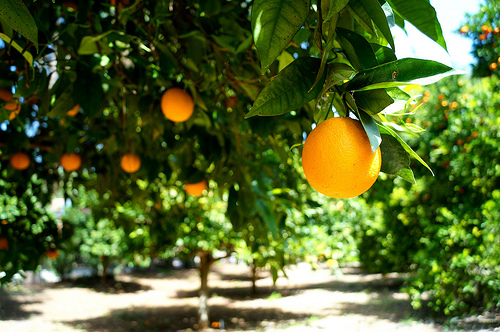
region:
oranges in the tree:
[5, 61, 368, 191]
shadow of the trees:
[103, 294, 278, 329]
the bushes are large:
[410, 138, 484, 307]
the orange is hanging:
[310, 123, 377, 194]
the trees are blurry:
[80, 210, 236, 290]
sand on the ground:
[303, 279, 368, 318]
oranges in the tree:
[0, 131, 186, 167]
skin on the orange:
[316, 145, 351, 197]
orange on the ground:
[209, 318, 229, 324]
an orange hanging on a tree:
[296, 109, 383, 202]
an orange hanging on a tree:
[159, 86, 198, 123]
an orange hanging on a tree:
[119, 150, 142, 175]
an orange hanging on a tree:
[179, 171, 209, 199]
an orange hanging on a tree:
[58, 147, 83, 173]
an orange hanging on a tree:
[10, 152, 27, 170]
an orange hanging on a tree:
[0, 88, 27, 122]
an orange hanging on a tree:
[43, 247, 60, 259]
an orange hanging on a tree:
[0, 236, 13, 253]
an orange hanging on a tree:
[458, 22, 472, 34]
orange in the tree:
[157, 93, 198, 138]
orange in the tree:
[293, 114, 370, 205]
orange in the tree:
[118, 153, 159, 175]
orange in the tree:
[168, 163, 213, 200]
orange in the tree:
[51, 147, 86, 176]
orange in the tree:
[13, 155, 35, 175]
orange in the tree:
[3, 145, 35, 185]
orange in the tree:
[0, 99, 15, 136]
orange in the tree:
[446, 84, 466, 110]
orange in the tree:
[486, 58, 496, 74]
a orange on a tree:
[291, 108, 388, 203]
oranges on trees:
[20, 21, 386, 203]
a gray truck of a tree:
[195, 255, 210, 322]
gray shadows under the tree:
[295, 265, 395, 295]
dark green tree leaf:
[245, 56, 315, 116]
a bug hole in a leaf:
[351, 57, 451, 87]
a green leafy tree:
[402, 201, 497, 316]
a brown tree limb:
[219, 49, 244, 85]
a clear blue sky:
[405, 23, 464, 59]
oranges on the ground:
[208, 318, 220, 330]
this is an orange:
[237, 111, 405, 213]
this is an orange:
[156, 80, 200, 126]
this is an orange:
[175, 158, 218, 213]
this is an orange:
[110, 148, 150, 179]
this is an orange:
[56, 140, 87, 177]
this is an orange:
[1, 148, 43, 178]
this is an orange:
[42, 233, 77, 270]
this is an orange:
[44, 90, 103, 134]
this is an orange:
[33, 232, 66, 259]